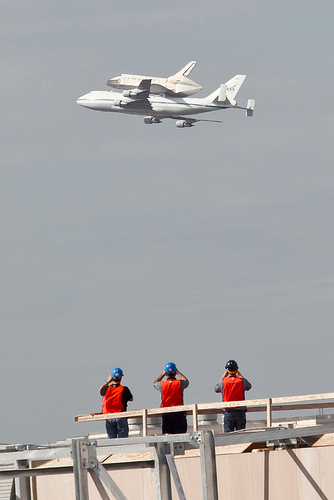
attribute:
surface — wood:
[7, 428, 331, 500]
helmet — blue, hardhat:
[164, 362, 178, 377]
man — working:
[154, 360, 190, 433]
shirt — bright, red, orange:
[159, 380, 183, 407]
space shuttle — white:
[109, 58, 203, 96]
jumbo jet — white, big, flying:
[77, 74, 259, 128]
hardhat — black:
[224, 358, 240, 375]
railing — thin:
[71, 394, 333, 425]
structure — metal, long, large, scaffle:
[1, 426, 323, 499]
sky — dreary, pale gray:
[2, 1, 333, 445]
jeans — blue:
[105, 416, 130, 440]